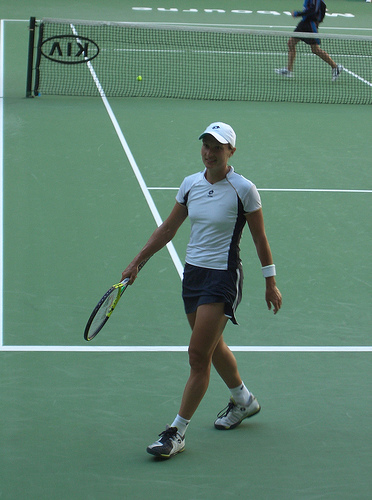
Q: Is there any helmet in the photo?
A: No, there are no helmets.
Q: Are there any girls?
A: No, there are no girls.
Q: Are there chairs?
A: No, there are no chairs.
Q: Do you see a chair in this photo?
A: No, there are no chairs.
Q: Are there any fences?
A: No, there are no fences.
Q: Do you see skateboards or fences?
A: No, there are no fences or skateboards.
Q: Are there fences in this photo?
A: No, there are no fences.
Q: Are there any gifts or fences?
A: No, there are no fences or gifts.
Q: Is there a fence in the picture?
A: No, there are no fences.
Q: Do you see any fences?
A: No, there are no fences.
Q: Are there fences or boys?
A: No, there are no fences or boys.